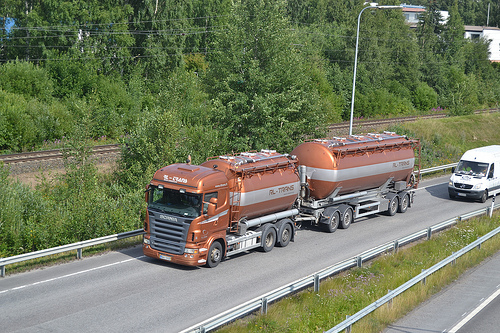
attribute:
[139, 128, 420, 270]
tanker — copper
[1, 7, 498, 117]
trees — here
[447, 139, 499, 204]
van — white, driving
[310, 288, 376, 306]
flowers — white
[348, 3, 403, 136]
lamp — tall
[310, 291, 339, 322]
grass — here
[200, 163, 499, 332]
road — clean, here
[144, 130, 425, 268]
truck — large, brown, here, orange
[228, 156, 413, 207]
stripe — silver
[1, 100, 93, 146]
shrubs — green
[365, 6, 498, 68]
building — peeking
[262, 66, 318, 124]
leaves — green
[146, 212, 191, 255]
grill — here